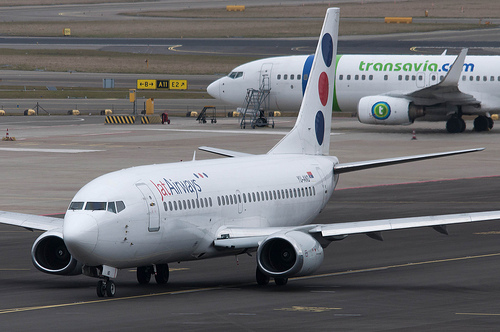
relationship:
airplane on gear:
[0, 6, 499, 298] [94, 277, 118, 297]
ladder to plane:
[239, 86, 268, 132] [204, 52, 499, 134]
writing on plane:
[356, 60, 475, 73] [204, 52, 499, 134]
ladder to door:
[239, 86, 268, 132] [259, 61, 274, 93]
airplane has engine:
[0, 6, 499, 298] [254, 228, 327, 279]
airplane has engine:
[0, 6, 499, 298] [30, 229, 78, 275]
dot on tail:
[320, 32, 336, 68] [271, 6, 344, 156]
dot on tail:
[318, 71, 330, 107] [271, 6, 344, 156]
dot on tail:
[313, 109, 327, 145] [271, 6, 344, 156]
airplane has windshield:
[0, 6, 499, 298] [67, 200, 126, 213]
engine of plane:
[357, 94, 424, 124] [204, 52, 499, 134]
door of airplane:
[136, 182, 163, 231] [0, 6, 499, 298]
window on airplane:
[163, 201, 169, 214] [0, 6, 499, 298]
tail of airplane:
[271, 6, 344, 156] [0, 6, 499, 298]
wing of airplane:
[217, 211, 498, 248] [0, 6, 499, 298]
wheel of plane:
[445, 116, 467, 134] [204, 52, 499, 134]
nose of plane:
[206, 75, 227, 102] [204, 52, 499, 134]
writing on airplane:
[150, 177, 202, 200] [0, 6, 499, 298]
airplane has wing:
[0, 6, 499, 298] [217, 211, 498, 248]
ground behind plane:
[1, 46, 271, 79] [204, 52, 499, 134]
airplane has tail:
[0, 6, 499, 298] [271, 6, 344, 156]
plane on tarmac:
[204, 52, 499, 134] [1, 117, 499, 213]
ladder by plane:
[239, 86, 268, 132] [204, 52, 499, 134]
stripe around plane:
[300, 49, 316, 96] [204, 52, 499, 134]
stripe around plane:
[333, 54, 342, 112] [204, 52, 499, 134]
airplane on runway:
[0, 6, 499, 298] [1, 173, 500, 331]